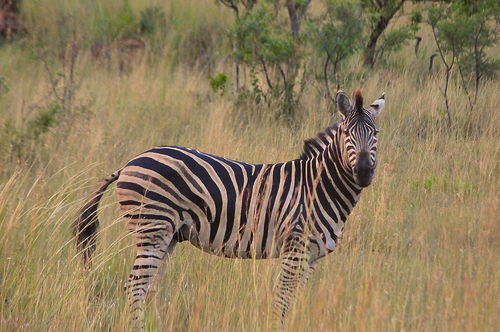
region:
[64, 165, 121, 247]
The tail of the zebra.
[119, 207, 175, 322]
The back legs of the zebra.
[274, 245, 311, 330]
The front legs of the zebra.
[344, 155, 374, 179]
The nose and nostrils of the zebra.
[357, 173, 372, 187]
The mouth area of the zebra.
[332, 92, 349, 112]
The left ear of the zebra.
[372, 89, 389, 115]
The right ear of the zebra.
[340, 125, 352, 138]
The left eye of the zebra.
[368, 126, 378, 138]
The right eye of the zebra.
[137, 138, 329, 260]
The stripes on the zebra's back.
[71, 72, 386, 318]
zebra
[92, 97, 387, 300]
zebra on plain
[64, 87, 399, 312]
striped zebra on plain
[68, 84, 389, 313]
black and white striped zebra on plain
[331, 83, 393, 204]
head of zebra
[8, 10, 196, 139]
long brown and green grass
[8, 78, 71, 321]
long brown and green grass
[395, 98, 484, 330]
long brown and green grass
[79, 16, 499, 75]
long brown and green grass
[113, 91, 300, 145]
long brown and green grass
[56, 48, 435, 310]
the zebra in the wild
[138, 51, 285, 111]
the long grass in the back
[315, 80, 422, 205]
the zebra looking at the camera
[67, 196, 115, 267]
the tail of zebra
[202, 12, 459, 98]
the tree behind the zebra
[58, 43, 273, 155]
bushes and more things behind the zebra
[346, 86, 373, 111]
the top of the zebra head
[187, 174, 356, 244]
the zebra is black and white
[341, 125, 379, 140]
the two eyes of the zebra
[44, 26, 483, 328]
a scene with a zebra in it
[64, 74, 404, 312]
a zebra standing in a field.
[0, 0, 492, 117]
a section of wild green plant life.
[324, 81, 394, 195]
the head of a zebra.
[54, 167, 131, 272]
the tail of a zebra.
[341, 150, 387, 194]
a zebra's nose.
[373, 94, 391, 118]
the left ear of a zebra.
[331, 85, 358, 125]
the right ear of a zebra.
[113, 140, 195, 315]
a zebra's backside.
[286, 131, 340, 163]
the mane of a zebra.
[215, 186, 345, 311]
the front half of a zebra.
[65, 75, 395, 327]
A sideview of an zebra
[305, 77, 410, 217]
Zebra is looking at the camera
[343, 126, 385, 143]
Zebra's eyes are black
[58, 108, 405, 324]
Zebra has black and white stripes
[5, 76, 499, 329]
Tall grass is dried out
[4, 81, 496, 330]
Tall grass is tan in color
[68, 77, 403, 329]
Zebra is in the foreground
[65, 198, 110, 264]
Zebra's tail is black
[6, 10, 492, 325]
Photo was taken in the daytime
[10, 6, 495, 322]
Photo was taken outdoors